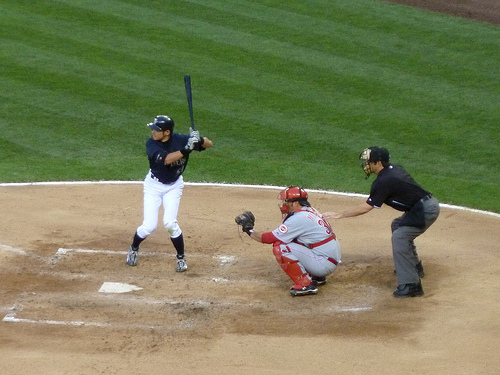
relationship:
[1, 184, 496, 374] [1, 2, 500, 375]
dirt on field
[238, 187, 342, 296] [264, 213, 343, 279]
catcher wearing uniform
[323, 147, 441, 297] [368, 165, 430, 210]
umpire wearing shirt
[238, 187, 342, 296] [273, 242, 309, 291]
catcher wearing shin guards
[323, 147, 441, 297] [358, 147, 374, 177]
umpire has face mask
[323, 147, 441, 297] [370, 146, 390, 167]
umpire has hat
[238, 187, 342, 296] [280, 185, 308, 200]
catcher has helmet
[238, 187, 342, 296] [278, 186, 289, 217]
catcher has mask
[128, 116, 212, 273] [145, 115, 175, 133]
batter has helmet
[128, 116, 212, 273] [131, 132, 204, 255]
player wearing uniform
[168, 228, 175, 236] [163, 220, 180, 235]
dirt on knee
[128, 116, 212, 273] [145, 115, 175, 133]
he wears helmet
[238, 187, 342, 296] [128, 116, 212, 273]
catcher behind batter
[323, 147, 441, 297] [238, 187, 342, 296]
umpire behind catcher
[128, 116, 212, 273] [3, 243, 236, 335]
batter in box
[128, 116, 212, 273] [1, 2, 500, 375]
people on field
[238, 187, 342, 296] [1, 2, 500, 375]
people on field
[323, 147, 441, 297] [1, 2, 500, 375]
people on field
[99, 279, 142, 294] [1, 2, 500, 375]
home plate on field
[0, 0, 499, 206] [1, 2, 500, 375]
grass on field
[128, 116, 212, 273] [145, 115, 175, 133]
man wearing helmet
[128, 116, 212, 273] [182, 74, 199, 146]
man holding bat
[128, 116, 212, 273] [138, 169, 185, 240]
man wearing pants